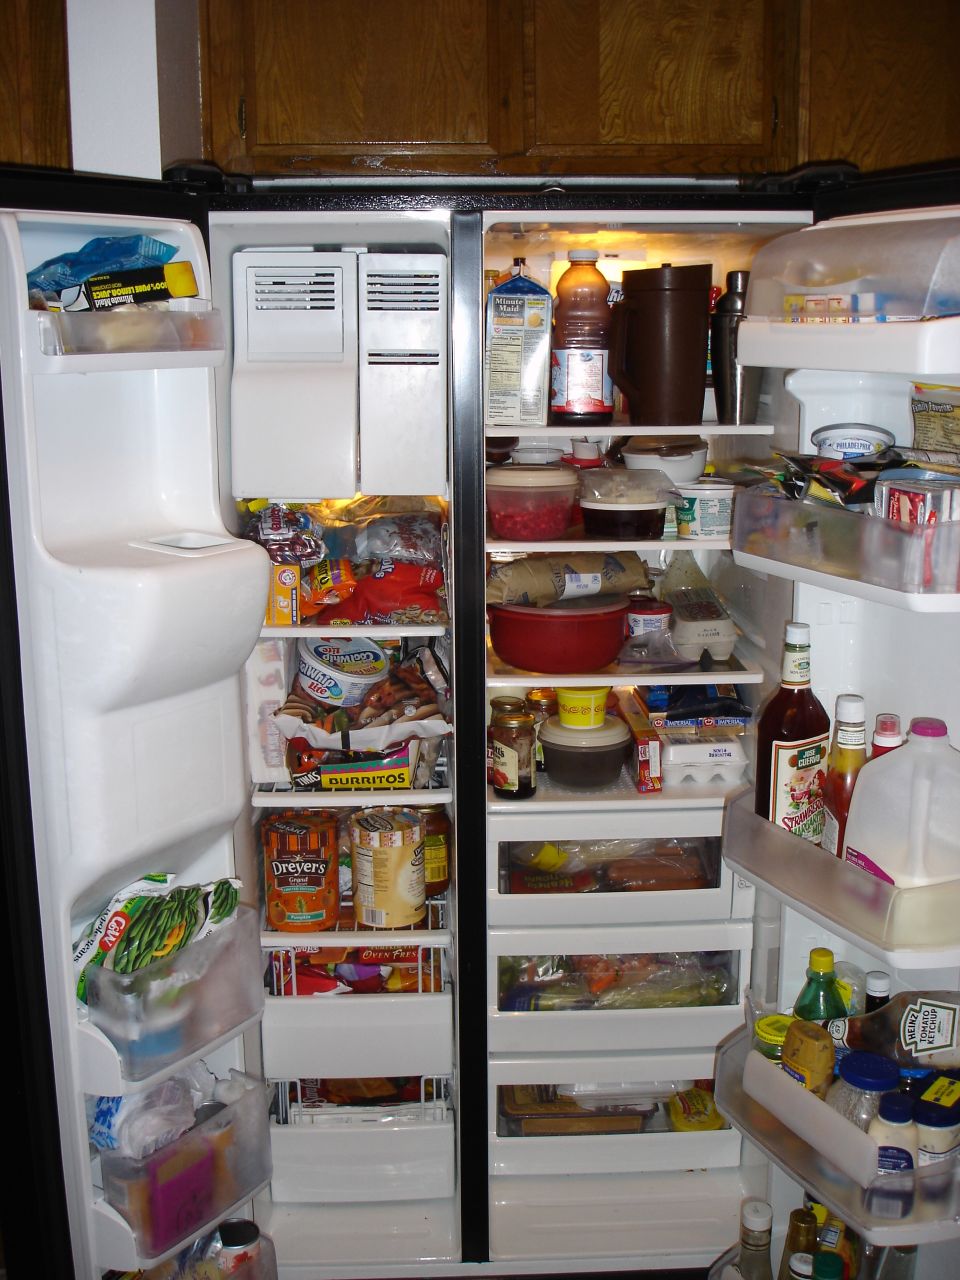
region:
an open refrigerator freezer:
[4, 171, 958, 1275]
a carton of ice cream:
[256, 814, 338, 936]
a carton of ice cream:
[351, 809, 427, 931]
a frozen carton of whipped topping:
[290, 634, 386, 705]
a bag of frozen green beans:
[72, 873, 242, 1010]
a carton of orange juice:
[480, 259, 549, 426]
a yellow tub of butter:
[556, 684, 609, 733]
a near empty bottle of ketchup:
[811, 994, 957, 1073]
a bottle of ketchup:
[818, 693, 866, 853]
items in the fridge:
[103, 234, 831, 1041]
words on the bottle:
[875, 990, 954, 1070]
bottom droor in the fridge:
[458, 1035, 767, 1180]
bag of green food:
[54, 839, 284, 1036]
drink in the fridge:
[514, 233, 658, 420]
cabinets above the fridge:
[100, 11, 832, 220]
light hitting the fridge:
[386, 148, 498, 270]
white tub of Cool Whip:
[296, 635, 392, 709]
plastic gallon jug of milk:
[836, 716, 958, 943]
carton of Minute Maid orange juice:
[481, 258, 553, 426]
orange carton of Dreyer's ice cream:
[264, 808, 340, 931]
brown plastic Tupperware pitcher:
[604, 261, 712, 422]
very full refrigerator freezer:
[0, 160, 958, 1277]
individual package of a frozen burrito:
[289, 736, 417, 790]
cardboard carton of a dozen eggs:
[665, 581, 741, 661]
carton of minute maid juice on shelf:
[475, 252, 569, 435]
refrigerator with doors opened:
[0, 171, 959, 1277]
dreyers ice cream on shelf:
[259, 812, 433, 938]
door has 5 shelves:
[711, 208, 959, 1277]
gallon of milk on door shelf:
[833, 708, 959, 953]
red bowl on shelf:
[483, 592, 631, 685]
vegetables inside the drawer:
[484, 919, 758, 1050]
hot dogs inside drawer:
[482, 811, 726, 923]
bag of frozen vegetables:
[70, 871, 253, 1024]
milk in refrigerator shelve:
[713, 613, 954, 973]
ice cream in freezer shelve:
[252, 788, 453, 953]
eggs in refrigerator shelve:
[480, 676, 763, 847]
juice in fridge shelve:
[471, 216, 778, 435]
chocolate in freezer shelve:
[220, 474, 444, 635]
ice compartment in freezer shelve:
[209, 212, 454, 506]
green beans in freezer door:
[58, 851, 278, 1101]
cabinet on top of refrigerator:
[6, 6, 952, 1271]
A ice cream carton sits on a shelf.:
[258, 801, 347, 934]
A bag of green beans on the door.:
[52, 863, 204, 1007]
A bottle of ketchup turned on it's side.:
[783, 983, 957, 1068]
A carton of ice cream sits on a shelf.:
[346, 808, 447, 931]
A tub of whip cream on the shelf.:
[283, 624, 383, 711]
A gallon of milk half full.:
[846, 705, 958, 942]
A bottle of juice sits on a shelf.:
[552, 243, 617, 424]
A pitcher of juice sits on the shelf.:
[610, 248, 714, 423]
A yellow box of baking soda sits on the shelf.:
[246, 560, 309, 623]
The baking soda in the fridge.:
[273, 555, 301, 629]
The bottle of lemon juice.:
[805, 943, 844, 1067]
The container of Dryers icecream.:
[253, 826, 339, 938]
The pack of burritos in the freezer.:
[318, 749, 414, 791]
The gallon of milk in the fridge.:
[841, 734, 958, 945]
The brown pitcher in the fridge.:
[604, 265, 702, 455]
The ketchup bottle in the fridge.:
[829, 691, 857, 863]